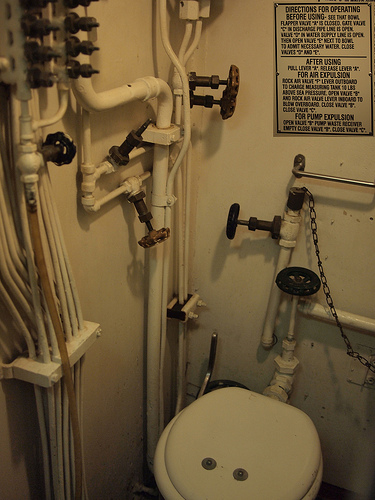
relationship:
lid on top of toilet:
[182, 427, 279, 473] [102, 436, 172, 491]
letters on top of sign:
[277, 27, 323, 91] [251, 0, 367, 142]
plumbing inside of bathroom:
[92, 261, 324, 396] [15, 319, 118, 390]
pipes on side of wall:
[262, 259, 295, 391] [207, 33, 260, 60]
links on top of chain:
[333, 345, 370, 366] [288, 207, 328, 297]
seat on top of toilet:
[306, 473, 318, 495] [102, 436, 172, 491]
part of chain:
[312, 240, 339, 250] [288, 207, 328, 297]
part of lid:
[238, 406, 257, 418] [182, 427, 279, 473]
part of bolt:
[53, 150, 75, 158] [11, 124, 99, 175]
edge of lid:
[231, 395, 269, 405] [182, 427, 279, 473]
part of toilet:
[279, 460, 313, 485] [102, 436, 172, 491]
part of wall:
[239, 7, 260, 16] [207, 33, 260, 60]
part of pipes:
[117, 99, 140, 104] [262, 259, 295, 391]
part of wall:
[117, 16, 129, 18] [207, 33, 260, 60]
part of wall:
[331, 144, 351, 151] [207, 33, 260, 60]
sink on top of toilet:
[284, 261, 321, 303] [102, 436, 172, 491]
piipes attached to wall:
[90, 87, 172, 199] [207, 33, 260, 60]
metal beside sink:
[200, 349, 243, 376] [284, 261, 321, 303]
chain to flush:
[288, 207, 328, 297] [198, 404, 312, 419]